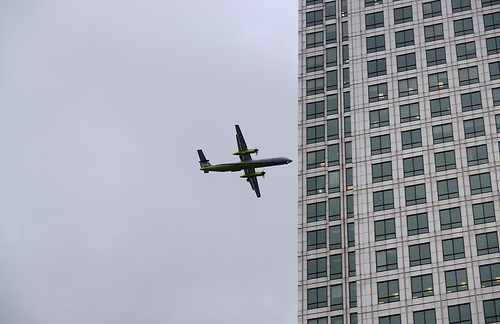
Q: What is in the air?
A: Plane.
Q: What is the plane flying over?
A: Building.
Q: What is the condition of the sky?
A: Cloudy.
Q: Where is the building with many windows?
A: On right.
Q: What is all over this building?
A: Windows.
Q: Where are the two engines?
A: On plane.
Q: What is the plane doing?
A: Flying.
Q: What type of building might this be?
A: Office building.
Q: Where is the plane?
A: Flying next to the building.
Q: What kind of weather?
A: Cloudy, overcast.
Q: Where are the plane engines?
A: Under the wing.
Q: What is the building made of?
A: Concrete.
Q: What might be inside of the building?
A: Offices.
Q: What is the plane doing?
A: Flying.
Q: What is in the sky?
A: Airplane.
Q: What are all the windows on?
A: Skyrise building.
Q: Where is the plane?
A: In the sky.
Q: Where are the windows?
A: On the building.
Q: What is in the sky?
A: An airplane.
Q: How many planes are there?
A: One.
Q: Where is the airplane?
A: In the sky.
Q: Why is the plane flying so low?
A: There is an airport nearby.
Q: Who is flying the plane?
A: A pilot.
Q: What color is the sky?
A: Grey.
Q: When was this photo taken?
A: During the day.